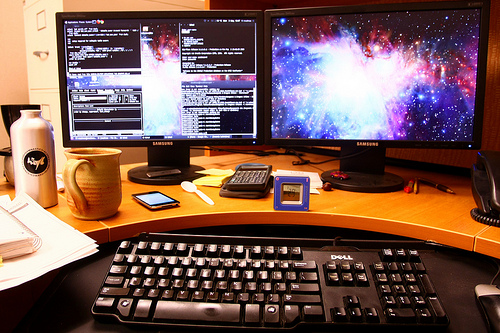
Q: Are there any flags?
A: No, there are no flags.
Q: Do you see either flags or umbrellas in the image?
A: No, there are no flags or umbrellas.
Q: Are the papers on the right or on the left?
A: The papers are on the left of the image.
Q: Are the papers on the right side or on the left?
A: The papers are on the left of the image.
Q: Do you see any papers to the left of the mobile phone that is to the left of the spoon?
A: Yes, there are papers to the left of the cellphone.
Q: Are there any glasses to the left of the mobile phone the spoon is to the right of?
A: No, there are papers to the left of the mobile phone.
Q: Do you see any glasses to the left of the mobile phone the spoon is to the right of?
A: No, there are papers to the left of the mobile phone.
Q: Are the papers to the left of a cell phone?
A: Yes, the papers are to the left of a cell phone.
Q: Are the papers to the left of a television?
A: No, the papers are to the left of a cell phone.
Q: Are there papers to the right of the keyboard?
A: No, the papers are to the left of the keyboard.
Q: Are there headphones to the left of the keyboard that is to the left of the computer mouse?
A: No, there are papers to the left of the keyboard.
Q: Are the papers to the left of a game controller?
A: No, the papers are to the left of a keyboard.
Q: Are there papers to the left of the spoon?
A: Yes, there are papers to the left of the spoon.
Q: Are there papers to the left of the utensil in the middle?
A: Yes, there are papers to the left of the spoon.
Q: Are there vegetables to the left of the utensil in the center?
A: No, there are papers to the left of the spoon.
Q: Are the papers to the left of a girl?
A: No, the papers are to the left of the spoon.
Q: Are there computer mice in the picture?
A: Yes, there is a computer mouse.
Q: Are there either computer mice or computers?
A: Yes, there is a computer mouse.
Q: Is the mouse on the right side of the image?
A: Yes, the mouse is on the right of the image.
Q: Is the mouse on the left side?
A: No, the mouse is on the right of the image.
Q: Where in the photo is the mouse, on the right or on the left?
A: The mouse is on the right of the image.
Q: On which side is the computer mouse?
A: The computer mouse is on the right of the image.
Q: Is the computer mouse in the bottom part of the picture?
A: Yes, the computer mouse is in the bottom of the image.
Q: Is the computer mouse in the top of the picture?
A: No, the computer mouse is in the bottom of the image.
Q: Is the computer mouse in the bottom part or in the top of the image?
A: The computer mouse is in the bottom of the image.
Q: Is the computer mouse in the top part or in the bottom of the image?
A: The computer mouse is in the bottom of the image.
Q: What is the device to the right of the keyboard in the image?
A: The device is a computer mouse.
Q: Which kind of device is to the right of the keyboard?
A: The device is a computer mouse.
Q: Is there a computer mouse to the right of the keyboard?
A: Yes, there is a computer mouse to the right of the keyboard.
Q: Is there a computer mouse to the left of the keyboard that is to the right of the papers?
A: No, the computer mouse is to the right of the keyboard.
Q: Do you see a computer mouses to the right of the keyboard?
A: No, there is a computer mouse to the right of the keyboard.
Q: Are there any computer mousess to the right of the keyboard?
A: No, there is a computer mouse to the right of the keyboard.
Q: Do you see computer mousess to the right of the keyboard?
A: No, there is a computer mouse to the right of the keyboard.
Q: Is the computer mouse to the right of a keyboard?
A: Yes, the computer mouse is to the right of a keyboard.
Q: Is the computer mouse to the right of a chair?
A: No, the computer mouse is to the right of a keyboard.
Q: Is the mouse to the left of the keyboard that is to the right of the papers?
A: No, the mouse is to the right of the keyboard.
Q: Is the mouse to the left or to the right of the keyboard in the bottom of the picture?
A: The mouse is to the right of the keyboard.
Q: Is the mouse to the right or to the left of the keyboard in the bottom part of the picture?
A: The mouse is to the right of the keyboard.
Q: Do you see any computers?
A: Yes, there is a computer.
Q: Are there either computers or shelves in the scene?
A: Yes, there is a computer.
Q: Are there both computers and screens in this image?
A: Yes, there are both a computer and a screen.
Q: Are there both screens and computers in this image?
A: Yes, there are both a computer and a screen.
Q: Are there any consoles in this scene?
A: No, there are no consoles.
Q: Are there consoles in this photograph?
A: No, there are no consoles.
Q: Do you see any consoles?
A: No, there are no consoles.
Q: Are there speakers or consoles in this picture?
A: No, there are no consoles or speakers.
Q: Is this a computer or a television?
A: This is a computer.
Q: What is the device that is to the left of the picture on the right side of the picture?
A: The device is a computer.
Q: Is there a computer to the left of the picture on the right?
A: Yes, there is a computer to the left of the picture.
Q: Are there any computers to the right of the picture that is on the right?
A: No, the computer is to the left of the picture.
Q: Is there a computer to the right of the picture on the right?
A: No, the computer is to the left of the picture.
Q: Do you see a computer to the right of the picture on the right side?
A: No, the computer is to the left of the picture.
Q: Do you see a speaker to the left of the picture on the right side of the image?
A: No, there is a computer to the left of the picture.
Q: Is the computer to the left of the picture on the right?
A: Yes, the computer is to the left of the picture.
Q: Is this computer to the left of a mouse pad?
A: No, the computer is to the left of the picture.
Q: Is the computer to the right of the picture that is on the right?
A: No, the computer is to the left of the picture.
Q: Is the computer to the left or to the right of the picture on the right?
A: The computer is to the left of the picture.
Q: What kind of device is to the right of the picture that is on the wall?
A: The device is a computer.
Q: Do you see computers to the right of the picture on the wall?
A: Yes, there is a computer to the right of the picture.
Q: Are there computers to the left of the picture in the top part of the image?
A: No, the computer is to the right of the picture.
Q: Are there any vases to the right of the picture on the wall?
A: No, there is a computer to the right of the picture.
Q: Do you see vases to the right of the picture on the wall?
A: No, there is a computer to the right of the picture.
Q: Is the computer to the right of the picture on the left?
A: Yes, the computer is to the right of the picture.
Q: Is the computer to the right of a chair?
A: No, the computer is to the right of the picture.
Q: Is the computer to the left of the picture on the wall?
A: No, the computer is to the right of the picture.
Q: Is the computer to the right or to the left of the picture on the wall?
A: The computer is to the right of the picture.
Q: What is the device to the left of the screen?
A: The device is a computer.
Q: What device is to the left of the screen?
A: The device is a computer.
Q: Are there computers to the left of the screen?
A: Yes, there is a computer to the left of the screen.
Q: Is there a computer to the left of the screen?
A: Yes, there is a computer to the left of the screen.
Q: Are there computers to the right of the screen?
A: No, the computer is to the left of the screen.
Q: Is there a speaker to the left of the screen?
A: No, there is a computer to the left of the screen.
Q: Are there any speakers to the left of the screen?
A: No, there is a computer to the left of the screen.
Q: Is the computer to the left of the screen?
A: Yes, the computer is to the left of the screen.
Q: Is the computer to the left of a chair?
A: No, the computer is to the left of the screen.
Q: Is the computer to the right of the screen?
A: No, the computer is to the left of the screen.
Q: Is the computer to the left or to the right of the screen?
A: The computer is to the left of the screen.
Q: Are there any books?
A: No, there are no books.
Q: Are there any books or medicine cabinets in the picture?
A: No, there are no books or medicine cabinets.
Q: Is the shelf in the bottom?
A: Yes, the shelf is in the bottom of the image.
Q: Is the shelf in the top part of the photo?
A: No, the shelf is in the bottom of the image.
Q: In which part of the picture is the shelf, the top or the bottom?
A: The shelf is in the bottom of the image.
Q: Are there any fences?
A: No, there are no fences.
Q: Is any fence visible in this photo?
A: No, there are no fences.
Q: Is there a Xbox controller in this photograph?
A: No, there are no Xbox controllers.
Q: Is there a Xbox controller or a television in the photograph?
A: No, there are no Xbox controllers or televisions.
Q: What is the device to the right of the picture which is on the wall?
A: The device is a computer monitor.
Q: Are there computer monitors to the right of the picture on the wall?
A: Yes, there is a computer monitor to the right of the picture.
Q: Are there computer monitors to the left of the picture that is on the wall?
A: No, the computer monitor is to the right of the picture.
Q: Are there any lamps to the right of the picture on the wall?
A: No, there is a computer monitor to the right of the picture.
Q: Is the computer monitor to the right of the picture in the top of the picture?
A: Yes, the computer monitor is to the right of the picture.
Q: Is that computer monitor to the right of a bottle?
A: No, the computer monitor is to the right of the picture.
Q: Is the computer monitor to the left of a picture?
A: No, the computer monitor is to the right of a picture.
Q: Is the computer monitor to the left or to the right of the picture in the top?
A: The computer monitor is to the right of the picture.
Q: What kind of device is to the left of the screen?
A: The device is a computer monitor.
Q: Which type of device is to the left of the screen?
A: The device is a computer monitor.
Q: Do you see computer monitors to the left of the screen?
A: Yes, there is a computer monitor to the left of the screen.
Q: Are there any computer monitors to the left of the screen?
A: Yes, there is a computer monitor to the left of the screen.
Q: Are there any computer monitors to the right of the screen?
A: No, the computer monitor is to the left of the screen.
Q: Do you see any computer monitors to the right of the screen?
A: No, the computer monitor is to the left of the screen.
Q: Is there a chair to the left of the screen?
A: No, there is a computer monitor to the left of the screen.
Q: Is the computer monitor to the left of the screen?
A: Yes, the computer monitor is to the left of the screen.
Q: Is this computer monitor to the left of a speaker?
A: No, the computer monitor is to the left of the screen.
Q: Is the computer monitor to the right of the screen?
A: No, the computer monitor is to the left of the screen.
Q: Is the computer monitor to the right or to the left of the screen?
A: The computer monitor is to the left of the screen.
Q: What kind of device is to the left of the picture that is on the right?
A: The device is a computer monitor.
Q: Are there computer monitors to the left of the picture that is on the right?
A: Yes, there is a computer monitor to the left of the picture.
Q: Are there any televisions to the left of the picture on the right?
A: No, there is a computer monitor to the left of the picture.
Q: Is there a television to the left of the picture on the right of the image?
A: No, there is a computer monitor to the left of the picture.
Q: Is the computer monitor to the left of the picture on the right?
A: Yes, the computer monitor is to the left of the picture.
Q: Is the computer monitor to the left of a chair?
A: No, the computer monitor is to the left of the picture.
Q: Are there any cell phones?
A: Yes, there is a cell phone.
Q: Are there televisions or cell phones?
A: Yes, there is a cell phone.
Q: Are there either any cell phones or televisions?
A: Yes, there is a cell phone.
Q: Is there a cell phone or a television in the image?
A: Yes, there is a cell phone.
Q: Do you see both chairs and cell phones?
A: No, there is a cell phone but no chairs.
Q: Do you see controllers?
A: No, there are no controllers.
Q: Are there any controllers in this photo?
A: No, there are no controllers.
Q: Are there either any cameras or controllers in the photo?
A: No, there are no controllers or cameras.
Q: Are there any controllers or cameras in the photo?
A: No, there are no controllers or cameras.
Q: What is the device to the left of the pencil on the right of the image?
A: The device is a cell phone.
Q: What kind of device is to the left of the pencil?
A: The device is a cell phone.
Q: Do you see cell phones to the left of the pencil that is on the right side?
A: Yes, there is a cell phone to the left of the pencil.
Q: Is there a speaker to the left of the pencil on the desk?
A: No, there is a cell phone to the left of the pencil.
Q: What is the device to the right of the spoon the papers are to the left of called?
A: The device is a cell phone.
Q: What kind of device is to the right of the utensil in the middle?
A: The device is a cell phone.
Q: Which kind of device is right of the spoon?
A: The device is a cell phone.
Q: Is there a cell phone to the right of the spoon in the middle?
A: Yes, there is a cell phone to the right of the spoon.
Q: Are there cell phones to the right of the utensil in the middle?
A: Yes, there is a cell phone to the right of the spoon.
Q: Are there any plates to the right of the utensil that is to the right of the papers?
A: No, there is a cell phone to the right of the spoon.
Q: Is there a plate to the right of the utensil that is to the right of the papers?
A: No, there is a cell phone to the right of the spoon.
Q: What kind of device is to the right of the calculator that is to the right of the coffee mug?
A: The device is a cell phone.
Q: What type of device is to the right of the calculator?
A: The device is a cell phone.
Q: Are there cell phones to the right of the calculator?
A: Yes, there is a cell phone to the right of the calculator.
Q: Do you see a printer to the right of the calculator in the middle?
A: No, there is a cell phone to the right of the calculator.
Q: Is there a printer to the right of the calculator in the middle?
A: No, there is a cell phone to the right of the calculator.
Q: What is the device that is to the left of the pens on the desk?
A: The device is a cell phone.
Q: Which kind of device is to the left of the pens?
A: The device is a cell phone.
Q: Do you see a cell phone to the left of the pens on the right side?
A: Yes, there is a cell phone to the left of the pens.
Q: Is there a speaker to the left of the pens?
A: No, there is a cell phone to the left of the pens.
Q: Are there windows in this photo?
A: Yes, there is a window.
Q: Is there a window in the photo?
A: Yes, there is a window.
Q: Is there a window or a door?
A: Yes, there is a window.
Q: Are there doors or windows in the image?
A: Yes, there is a window.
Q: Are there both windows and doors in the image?
A: No, there is a window but no doors.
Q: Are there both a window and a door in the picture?
A: No, there is a window but no doors.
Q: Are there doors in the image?
A: No, there are no doors.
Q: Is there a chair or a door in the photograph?
A: No, there are no doors or chairs.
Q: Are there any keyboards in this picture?
A: Yes, there is a keyboard.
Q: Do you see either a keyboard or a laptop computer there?
A: Yes, there is a keyboard.